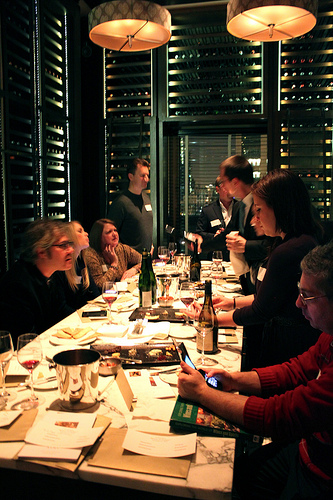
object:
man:
[179, 243, 333, 493]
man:
[198, 175, 237, 261]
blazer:
[194, 199, 238, 257]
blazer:
[206, 200, 255, 254]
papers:
[1, 415, 104, 449]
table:
[0, 254, 251, 498]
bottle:
[190, 239, 200, 282]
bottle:
[138, 253, 154, 310]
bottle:
[197, 282, 218, 354]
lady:
[85, 219, 142, 293]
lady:
[180, 176, 319, 346]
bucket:
[52, 348, 99, 411]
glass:
[102, 282, 118, 323]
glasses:
[297, 281, 332, 302]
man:
[191, 155, 281, 272]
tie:
[238, 200, 245, 235]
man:
[107, 157, 154, 260]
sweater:
[113, 190, 153, 254]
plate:
[93, 343, 183, 368]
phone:
[178, 342, 225, 391]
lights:
[89, 1, 171, 52]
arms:
[176, 329, 331, 438]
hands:
[178, 361, 211, 407]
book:
[168, 392, 264, 444]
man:
[1, 221, 74, 351]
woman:
[64, 221, 92, 313]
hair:
[23, 220, 71, 265]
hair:
[64, 220, 90, 289]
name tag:
[142, 191, 153, 211]